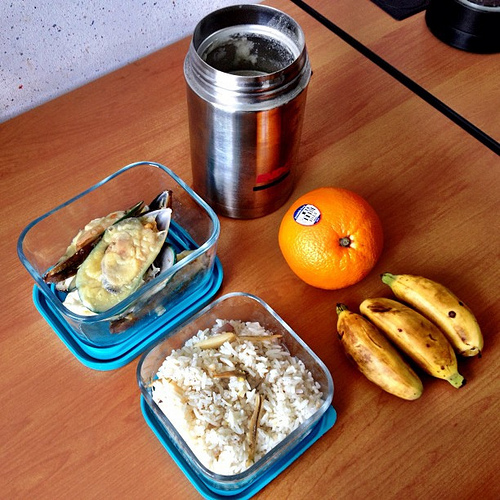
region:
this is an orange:
[288, 199, 371, 276]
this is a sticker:
[296, 205, 318, 226]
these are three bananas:
[331, 271, 478, 401]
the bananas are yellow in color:
[391, 290, 423, 379]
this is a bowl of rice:
[158, 327, 300, 449]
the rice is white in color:
[280, 386, 306, 408]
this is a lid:
[92, 350, 123, 370]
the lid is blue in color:
[93, 347, 123, 364]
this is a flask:
[196, 71, 293, 184]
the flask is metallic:
[216, 119, 274, 179]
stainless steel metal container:
[174, 1, 321, 235]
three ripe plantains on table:
[329, 265, 489, 409]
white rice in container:
[157, 309, 302, 454]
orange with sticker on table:
[271, 180, 390, 290]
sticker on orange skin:
[286, 197, 326, 235]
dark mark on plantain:
[368, 300, 397, 322]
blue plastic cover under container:
[49, 314, 136, 376]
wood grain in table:
[384, 429, 474, 472]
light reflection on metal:
[209, 63, 251, 155]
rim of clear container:
[252, 293, 296, 332]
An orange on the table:
[277, 188, 374, 285]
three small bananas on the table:
[329, 268, 484, 408]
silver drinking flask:
[163, 10, 343, 217]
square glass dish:
[117, 291, 354, 493]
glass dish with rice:
[148, 298, 341, 477]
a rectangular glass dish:
[16, 153, 229, 330]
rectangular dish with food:
[7, 160, 236, 313]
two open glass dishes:
[12, 166, 337, 478]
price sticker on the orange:
[285, 199, 330, 225]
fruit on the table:
[256, 181, 491, 398]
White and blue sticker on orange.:
[274, 182, 323, 271]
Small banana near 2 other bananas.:
[326, 295, 451, 475]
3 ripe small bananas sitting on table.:
[391, 277, 460, 417]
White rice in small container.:
[172, 350, 292, 466]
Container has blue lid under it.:
[194, 468, 202, 488]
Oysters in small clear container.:
[48, 195, 205, 310]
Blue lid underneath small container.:
[40, 326, 136, 409]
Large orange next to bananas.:
[264, 146, 432, 352]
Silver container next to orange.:
[168, 81, 328, 175]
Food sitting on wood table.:
[70, 259, 487, 403]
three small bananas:
[334, 266, 482, 403]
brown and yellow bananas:
[325, 272, 482, 402]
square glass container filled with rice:
[138, 287, 336, 492]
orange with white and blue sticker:
[278, 183, 382, 289]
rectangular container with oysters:
[19, 157, 229, 315]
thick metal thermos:
[180, 1, 309, 223]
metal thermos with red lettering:
[181, 4, 311, 224]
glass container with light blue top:
[136, 291, 335, 496]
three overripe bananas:
[324, 270, 489, 398]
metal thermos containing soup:
[180, 1, 315, 215]